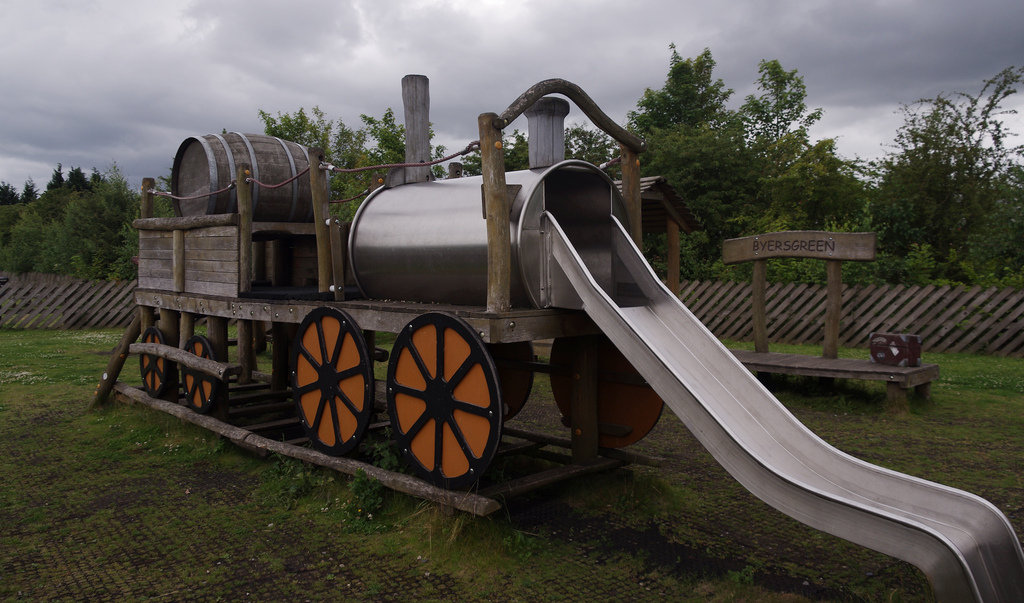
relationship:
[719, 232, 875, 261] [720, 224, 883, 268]
letters on sign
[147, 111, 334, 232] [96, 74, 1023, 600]
barrel on top of playground equipment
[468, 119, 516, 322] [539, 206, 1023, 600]
pole at top of slide